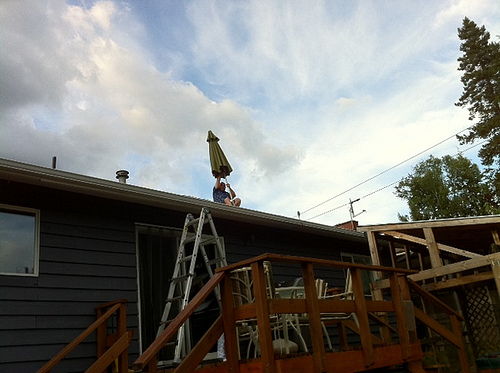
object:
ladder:
[151, 207, 228, 364]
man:
[213, 175, 241, 207]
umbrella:
[206, 129, 234, 179]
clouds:
[0, 0, 110, 118]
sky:
[0, 0, 499, 228]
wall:
[0, 182, 140, 373]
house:
[0, 156, 399, 372]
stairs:
[38, 271, 242, 371]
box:
[272, 338, 298, 356]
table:
[274, 286, 305, 299]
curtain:
[342, 252, 374, 296]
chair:
[244, 286, 308, 358]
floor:
[196, 342, 427, 373]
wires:
[290, 120, 500, 220]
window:
[0, 208, 40, 275]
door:
[136, 223, 226, 360]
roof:
[0, 157, 367, 241]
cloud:
[67, 1, 307, 186]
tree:
[452, 15, 500, 171]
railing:
[37, 256, 467, 373]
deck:
[38, 254, 467, 373]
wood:
[274, 342, 422, 372]